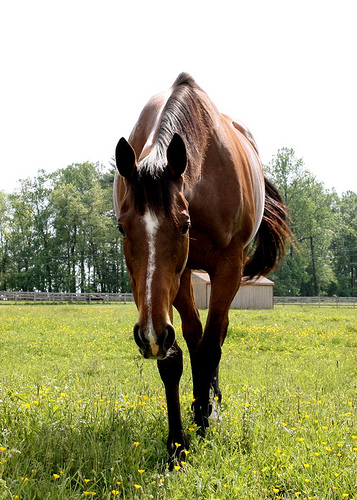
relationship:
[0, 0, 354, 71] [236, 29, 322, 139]
clouds in sky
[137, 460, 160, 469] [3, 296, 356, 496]
flower in field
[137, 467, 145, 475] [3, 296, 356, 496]
flower in field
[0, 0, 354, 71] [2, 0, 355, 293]
clouds in sky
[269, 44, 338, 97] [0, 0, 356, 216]
white clouds in sky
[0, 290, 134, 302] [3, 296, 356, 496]
fencing on field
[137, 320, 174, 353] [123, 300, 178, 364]
nostrils on nose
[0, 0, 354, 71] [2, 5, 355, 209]
clouds in sky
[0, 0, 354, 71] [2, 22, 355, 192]
clouds in sky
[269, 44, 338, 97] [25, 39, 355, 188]
white clouds in sky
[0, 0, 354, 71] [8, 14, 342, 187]
clouds in sky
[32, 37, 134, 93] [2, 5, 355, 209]
clouds in sky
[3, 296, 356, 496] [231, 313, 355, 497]
field of grass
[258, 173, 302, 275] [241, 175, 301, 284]
hair on tail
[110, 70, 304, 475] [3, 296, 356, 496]
horse in field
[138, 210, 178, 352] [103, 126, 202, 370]
stripe on head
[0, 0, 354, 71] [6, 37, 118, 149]
clouds in sky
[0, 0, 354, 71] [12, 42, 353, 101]
clouds in sky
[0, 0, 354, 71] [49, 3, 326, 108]
clouds in sky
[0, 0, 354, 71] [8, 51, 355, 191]
clouds in sky